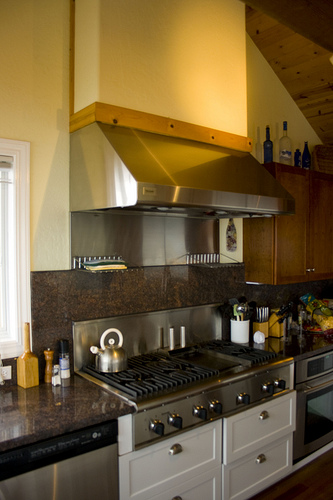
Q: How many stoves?
A: One.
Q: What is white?
A: Drawers.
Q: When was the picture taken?
A: Daytime.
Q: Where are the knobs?
A: On the front of the stove.